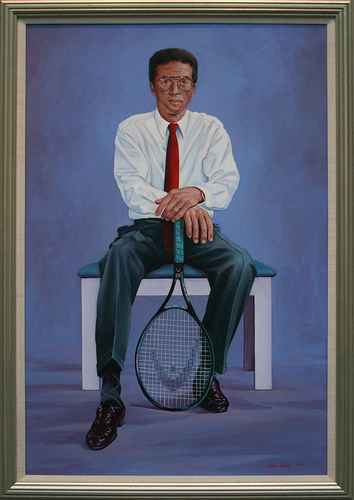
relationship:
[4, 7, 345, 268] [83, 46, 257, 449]
painting of man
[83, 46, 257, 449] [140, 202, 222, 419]
man with racket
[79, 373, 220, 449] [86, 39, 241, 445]
shoes on man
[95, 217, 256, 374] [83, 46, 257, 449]
pants on man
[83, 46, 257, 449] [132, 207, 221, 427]
man leaning on tennis racket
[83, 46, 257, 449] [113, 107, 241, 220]
man wearing shirt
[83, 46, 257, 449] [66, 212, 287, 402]
man sitting on bench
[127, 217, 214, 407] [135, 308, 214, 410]
racket standing on head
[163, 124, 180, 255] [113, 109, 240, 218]
tie hanging down torso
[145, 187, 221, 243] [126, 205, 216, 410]
hands resting on racket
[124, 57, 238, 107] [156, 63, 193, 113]
glasses on face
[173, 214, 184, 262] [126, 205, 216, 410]
blue handle on racket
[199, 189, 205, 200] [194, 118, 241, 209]
watch poking out from under shirt sleeve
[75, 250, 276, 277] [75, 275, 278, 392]
cushion on chair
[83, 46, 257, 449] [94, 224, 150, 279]
man wearing pants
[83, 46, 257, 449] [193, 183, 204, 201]
man wearing watch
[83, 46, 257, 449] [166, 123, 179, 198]
man wearing tie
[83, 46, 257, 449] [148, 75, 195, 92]
man wearing glasses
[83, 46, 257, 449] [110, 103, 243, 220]
man wearing shirt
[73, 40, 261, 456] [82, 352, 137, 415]
man wearing socks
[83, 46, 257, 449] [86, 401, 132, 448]
man wearing shoes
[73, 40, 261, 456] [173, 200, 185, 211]
man wearing gold ring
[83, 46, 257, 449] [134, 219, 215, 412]
man holding racket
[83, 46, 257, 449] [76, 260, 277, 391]
man sitting in bench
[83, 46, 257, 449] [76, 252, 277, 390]
man sitting on bench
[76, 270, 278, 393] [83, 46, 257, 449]
bench under man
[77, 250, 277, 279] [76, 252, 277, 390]
cushion on bench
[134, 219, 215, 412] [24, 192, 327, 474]
racket in forefront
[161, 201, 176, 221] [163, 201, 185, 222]
finger on finger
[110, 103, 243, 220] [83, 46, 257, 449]
shirt on man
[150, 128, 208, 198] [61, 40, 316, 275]
tie on man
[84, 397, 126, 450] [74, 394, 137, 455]
shoe on foot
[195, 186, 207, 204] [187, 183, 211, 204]
watch on wrist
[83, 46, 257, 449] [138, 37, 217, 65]
man has hair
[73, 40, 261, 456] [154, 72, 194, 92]
man wearing glasses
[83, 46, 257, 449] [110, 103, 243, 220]
man has shirt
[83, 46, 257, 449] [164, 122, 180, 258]
man has tie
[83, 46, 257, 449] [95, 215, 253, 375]
man has pants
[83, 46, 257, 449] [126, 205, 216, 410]
man holds racket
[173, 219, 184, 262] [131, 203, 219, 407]
blue handle on racket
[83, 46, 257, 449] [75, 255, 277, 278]
man sits on blue cushion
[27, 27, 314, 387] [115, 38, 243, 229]
background behind man